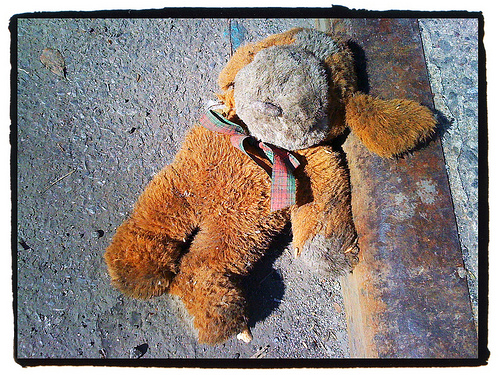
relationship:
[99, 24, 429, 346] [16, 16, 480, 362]
bear on ground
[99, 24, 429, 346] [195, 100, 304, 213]
bear has ribbon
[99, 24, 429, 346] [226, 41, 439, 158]
bear has ears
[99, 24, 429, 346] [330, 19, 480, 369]
bear on curb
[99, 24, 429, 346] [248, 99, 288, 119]
bear has mouth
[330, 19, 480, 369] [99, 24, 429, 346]
curb near bear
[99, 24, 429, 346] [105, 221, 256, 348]
bear has feet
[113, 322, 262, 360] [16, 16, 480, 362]
pebble on ground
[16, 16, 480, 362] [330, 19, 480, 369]
ground near curb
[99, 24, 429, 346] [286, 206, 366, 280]
bear has paws